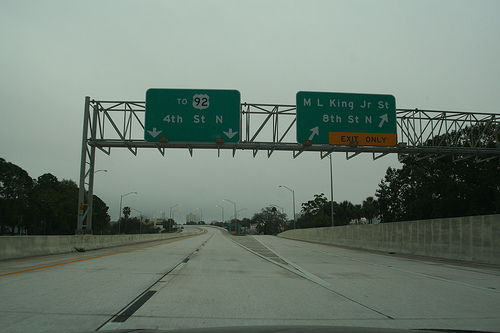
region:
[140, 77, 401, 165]
green highway signs suspended over road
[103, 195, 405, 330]
long empty highway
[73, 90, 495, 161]
stainless steel support for signs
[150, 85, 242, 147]
large green sign with white and black print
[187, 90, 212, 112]
small route sign with black printed numbers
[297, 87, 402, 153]
large green sign with yellow white and black printing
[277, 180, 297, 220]
tall steel street light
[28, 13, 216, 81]
cloudy grey sky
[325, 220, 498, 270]
concrete barrier wall on highway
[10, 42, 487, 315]
lonely scene of an empty roadway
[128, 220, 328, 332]
A highway and exit ramp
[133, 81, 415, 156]
Signs above a highway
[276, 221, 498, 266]
A concrete wall near the highway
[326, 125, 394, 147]
Sign that says Exit Only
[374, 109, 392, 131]
White arrow on green sign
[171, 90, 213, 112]
Sign that says To 92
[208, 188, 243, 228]
Street lights on near a highway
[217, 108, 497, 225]
Trees near the highway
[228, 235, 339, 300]
White lines on a road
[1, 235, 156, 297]
Yellow line on a road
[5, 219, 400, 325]
road is clear of cars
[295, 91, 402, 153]
highway street sign is green and white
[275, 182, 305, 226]
light pole on side of highway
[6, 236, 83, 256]
concrete barrier on road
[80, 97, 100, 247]
steel poles holding up sign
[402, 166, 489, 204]
trees on side of highway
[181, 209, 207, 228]
building is blurry in background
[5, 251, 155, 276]
yellow painted line on highway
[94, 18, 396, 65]
sky is cloudy in photo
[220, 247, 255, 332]
highway is made of concrete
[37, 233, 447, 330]
highway has no other cars on it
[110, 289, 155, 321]
black line on road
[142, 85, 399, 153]
two traffic signs above the freeway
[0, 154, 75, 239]
trees along the side of the highway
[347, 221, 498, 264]
wall along the freeway is tall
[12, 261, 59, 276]
orange line on the side of the road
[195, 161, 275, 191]
the sky is grey and cloudy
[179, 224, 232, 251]
curve in the road ahead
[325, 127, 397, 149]
part of sign says "exit only"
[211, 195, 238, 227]
street lights are on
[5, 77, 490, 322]
elevated traffic signs over roadway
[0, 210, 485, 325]
empty lanes of roadway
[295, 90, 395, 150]
green sign with yellow panel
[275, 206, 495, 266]
wire fence on side of ramp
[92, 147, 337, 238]
lampposts on either side of road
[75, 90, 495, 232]
metal structure and supports over lanes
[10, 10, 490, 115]
gray sky over signs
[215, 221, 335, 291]
triangular divider between lanes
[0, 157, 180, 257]
trees and bushes behind low partition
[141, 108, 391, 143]
white arrows on signs